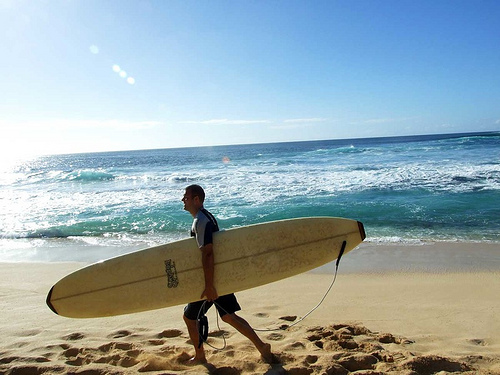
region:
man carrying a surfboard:
[40, 174, 368, 369]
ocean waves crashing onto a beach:
[2, 129, 497, 291]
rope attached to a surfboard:
[193, 238, 348, 350]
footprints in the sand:
[5, 310, 477, 373]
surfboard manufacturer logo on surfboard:
[158, 249, 184, 291]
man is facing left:
[177, 183, 282, 367]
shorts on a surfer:
[180, 282, 245, 324]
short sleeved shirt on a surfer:
[185, 206, 225, 255]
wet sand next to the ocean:
[2, 237, 499, 279]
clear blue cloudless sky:
[1, 0, 498, 152]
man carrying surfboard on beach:
[43, 182, 378, 367]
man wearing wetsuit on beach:
[156, 170, 217, 250]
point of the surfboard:
[39, 279, 84, 336]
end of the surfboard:
[329, 205, 381, 264]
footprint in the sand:
[279, 305, 310, 332]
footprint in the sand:
[161, 328, 185, 338]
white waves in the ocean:
[412, 174, 434, 189]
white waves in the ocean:
[311, 164, 348, 177]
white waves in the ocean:
[87, 198, 112, 213]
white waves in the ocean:
[461, 182, 491, 196]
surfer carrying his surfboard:
[44, 180, 376, 360]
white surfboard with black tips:
[48, 217, 367, 322]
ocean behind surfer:
[6, 142, 498, 229]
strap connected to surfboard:
[180, 268, 360, 353]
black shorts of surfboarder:
[185, 292, 242, 324]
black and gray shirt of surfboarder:
[187, 211, 220, 253]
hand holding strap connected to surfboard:
[189, 287, 228, 352]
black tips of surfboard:
[43, 213, 371, 321]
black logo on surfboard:
[154, 253, 180, 288]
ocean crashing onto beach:
[1, 206, 491, 247]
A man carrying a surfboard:
[40, 176, 395, 373]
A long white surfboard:
[40, 211, 381, 313]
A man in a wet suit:
[171, 173, 253, 360]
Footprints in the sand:
[58, 336, 429, 368]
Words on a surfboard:
[158, 255, 181, 291]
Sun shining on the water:
[1, 101, 99, 240]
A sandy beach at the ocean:
[239, 160, 499, 332]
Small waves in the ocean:
[288, 132, 498, 197]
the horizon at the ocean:
[133, 113, 474, 162]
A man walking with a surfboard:
[38, 165, 408, 342]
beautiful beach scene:
[0, 18, 489, 367]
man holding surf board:
[48, 174, 371, 374]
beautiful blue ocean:
[11, 128, 493, 248]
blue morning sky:
[0, 5, 492, 130]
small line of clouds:
[0, 110, 486, 130]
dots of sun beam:
[76, 35, 133, 105]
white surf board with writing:
[38, 215, 374, 316]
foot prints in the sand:
[0, 305, 478, 365]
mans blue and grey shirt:
[188, 207, 218, 248]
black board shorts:
[182, 294, 245, 336]